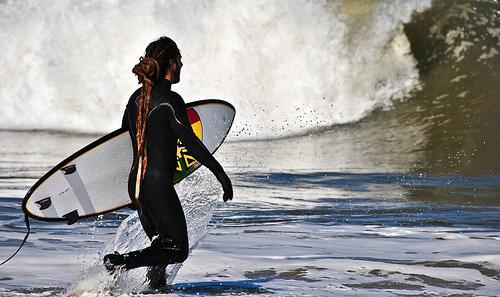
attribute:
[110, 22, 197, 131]
hair — long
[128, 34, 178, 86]
dreaded hair — dreaded 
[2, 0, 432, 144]
big wave — big 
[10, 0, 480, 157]
water — rough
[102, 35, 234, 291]
man — light 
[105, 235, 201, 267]
leg — raised